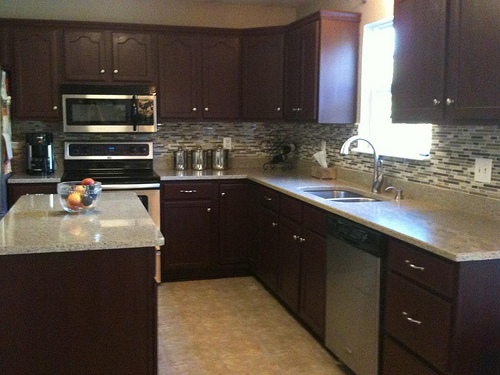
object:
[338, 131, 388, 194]
faucet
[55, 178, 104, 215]
fruit bowl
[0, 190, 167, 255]
counter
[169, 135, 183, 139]
tiles on wall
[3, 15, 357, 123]
cabinet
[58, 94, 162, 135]
microwave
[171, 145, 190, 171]
metal canisters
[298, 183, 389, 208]
sink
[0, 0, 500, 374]
kitchen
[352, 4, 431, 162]
window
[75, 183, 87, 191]
fruit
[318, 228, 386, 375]
dishwasher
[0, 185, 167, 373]
an island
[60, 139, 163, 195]
stove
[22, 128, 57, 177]
coffee maker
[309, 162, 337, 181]
box of kleenex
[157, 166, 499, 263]
counter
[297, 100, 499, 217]
wall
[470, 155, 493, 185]
light switch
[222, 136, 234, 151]
power outlet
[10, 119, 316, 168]
wall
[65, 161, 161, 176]
top of stove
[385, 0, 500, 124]
cupboards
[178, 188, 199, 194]
drawer handle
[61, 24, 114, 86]
cupboard doors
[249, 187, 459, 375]
cupboard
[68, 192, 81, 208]
orange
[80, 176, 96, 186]
apple